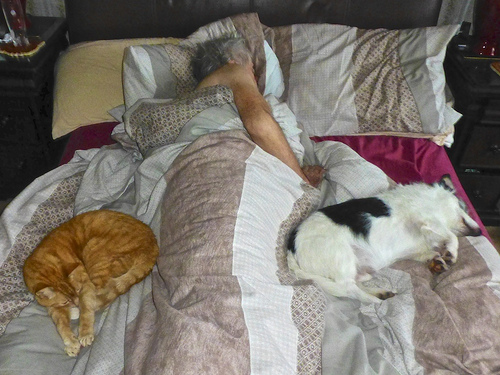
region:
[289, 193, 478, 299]
a white dog on the bed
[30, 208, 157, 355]
an orange cat on the bed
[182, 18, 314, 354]
a person sleeping in a bed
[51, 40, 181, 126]
a pillow on the bed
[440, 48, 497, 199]
a black end table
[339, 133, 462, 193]
a red bed sheet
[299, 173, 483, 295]
a sleeping dog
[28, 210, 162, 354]
a cat sleeping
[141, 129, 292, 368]
a white and grey bed spread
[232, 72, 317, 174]
the arm of the person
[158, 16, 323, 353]
A sleeping man in bed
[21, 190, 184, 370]
Orange cat with stripes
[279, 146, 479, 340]
Black and white dog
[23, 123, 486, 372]
Light pink striped blanket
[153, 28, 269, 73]
Salt and pepper gray hair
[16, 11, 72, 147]
Dark wood nightstand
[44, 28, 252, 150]
Light tan pillow case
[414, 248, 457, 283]
Light pink paw pad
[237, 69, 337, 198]
Hairy arm and hand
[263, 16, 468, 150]
Patterened striped pillow case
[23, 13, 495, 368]
A person sleeping with cat and dog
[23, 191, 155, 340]
A brown color cat on the bed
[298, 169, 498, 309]
White and black color dog on the bed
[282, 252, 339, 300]
Tail of the dog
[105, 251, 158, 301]
Tail of the cat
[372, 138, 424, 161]
Red color bedsheet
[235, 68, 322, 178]
Hand of the person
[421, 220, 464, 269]
Legs of the dog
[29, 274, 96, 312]
Head of the cat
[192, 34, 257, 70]
Head of the person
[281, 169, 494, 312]
"A black and white dog"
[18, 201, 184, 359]
"An orange cat"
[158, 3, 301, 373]
"This person is sleeping"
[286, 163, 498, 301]
"The dog is sleeping"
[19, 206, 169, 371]
"The cat is asleep"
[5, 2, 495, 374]
"All three are in the bed"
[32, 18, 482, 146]
"Pillows are pictured here"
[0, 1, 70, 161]
"A table is seen here"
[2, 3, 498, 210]
"There is two tables beside the bed"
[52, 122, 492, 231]
"Burgundy bed sheet"